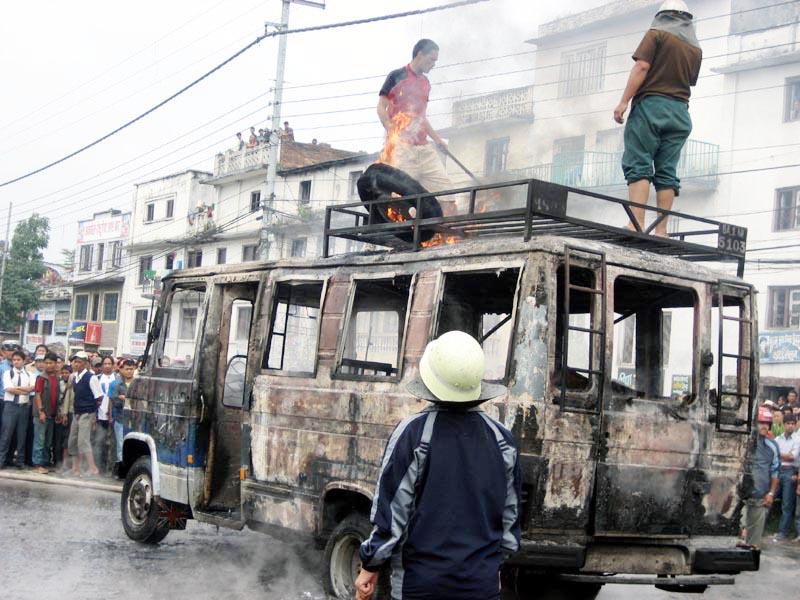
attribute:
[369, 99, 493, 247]
fire — Orange 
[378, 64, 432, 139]
shirt — black 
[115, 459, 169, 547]
tire — black 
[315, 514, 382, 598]
tire — black 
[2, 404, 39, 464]
pants — gray 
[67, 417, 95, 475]
pants — khaki